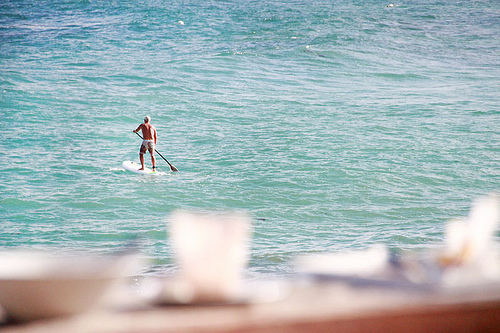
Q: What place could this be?
A: It is an ocean.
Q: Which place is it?
A: It is an ocean.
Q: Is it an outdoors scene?
A: Yes, it is outdoors.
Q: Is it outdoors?
A: Yes, it is outdoors.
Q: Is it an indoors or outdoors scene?
A: It is outdoors.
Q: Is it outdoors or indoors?
A: It is outdoors.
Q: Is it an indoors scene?
A: No, it is outdoors.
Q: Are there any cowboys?
A: No, there are no cowboys.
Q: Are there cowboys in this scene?
A: No, there are no cowboys.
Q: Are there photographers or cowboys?
A: No, there are no cowboys or photographers.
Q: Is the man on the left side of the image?
A: Yes, the man is on the left of the image.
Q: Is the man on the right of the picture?
A: No, the man is on the left of the image.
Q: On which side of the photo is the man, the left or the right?
A: The man is on the left of the image.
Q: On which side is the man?
A: The man is on the left of the image.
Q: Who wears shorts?
A: The man wears shorts.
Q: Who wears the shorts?
A: The man wears shorts.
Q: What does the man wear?
A: The man wears shorts.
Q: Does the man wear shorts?
A: Yes, the man wears shorts.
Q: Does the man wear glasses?
A: No, the man wears shorts.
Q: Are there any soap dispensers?
A: No, there are no soap dispensers.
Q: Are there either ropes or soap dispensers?
A: No, there are no soap dispensers or ropes.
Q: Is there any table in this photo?
A: Yes, there is a table.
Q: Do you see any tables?
A: Yes, there is a table.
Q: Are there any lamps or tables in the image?
A: Yes, there is a table.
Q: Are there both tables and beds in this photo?
A: No, there is a table but no beds.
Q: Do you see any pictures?
A: No, there are no pictures.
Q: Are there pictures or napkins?
A: No, there are no pictures or napkins.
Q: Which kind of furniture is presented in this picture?
A: The furniture is a table.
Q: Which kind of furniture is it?
A: The piece of furniture is a table.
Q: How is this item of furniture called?
A: This is a table.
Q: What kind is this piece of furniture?
A: This is a table.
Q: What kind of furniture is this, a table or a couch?
A: This is a table.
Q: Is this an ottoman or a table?
A: This is a table.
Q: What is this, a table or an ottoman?
A: This is a table.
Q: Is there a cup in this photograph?
A: Yes, there is a cup.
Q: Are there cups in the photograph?
A: Yes, there is a cup.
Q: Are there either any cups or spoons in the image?
A: Yes, there is a cup.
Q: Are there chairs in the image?
A: No, there are no chairs.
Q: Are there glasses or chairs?
A: No, there are no chairs or glasses.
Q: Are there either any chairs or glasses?
A: No, there are no chairs or glasses.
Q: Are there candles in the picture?
A: No, there are no candles.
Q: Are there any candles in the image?
A: No, there are no candles.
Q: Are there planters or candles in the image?
A: No, there are no candles or planters.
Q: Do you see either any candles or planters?
A: No, there are no candles or planters.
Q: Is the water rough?
A: Yes, the water is rough.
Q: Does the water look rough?
A: Yes, the water is rough.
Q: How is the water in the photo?
A: The water is rough.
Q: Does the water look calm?
A: No, the water is rough.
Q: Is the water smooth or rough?
A: The water is rough.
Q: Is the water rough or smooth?
A: The water is rough.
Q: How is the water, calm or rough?
A: The water is rough.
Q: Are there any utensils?
A: No, there are no utensils.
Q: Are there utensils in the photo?
A: No, there are no utensils.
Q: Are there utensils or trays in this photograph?
A: No, there are no utensils or trays.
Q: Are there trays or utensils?
A: No, there are no utensils or trays.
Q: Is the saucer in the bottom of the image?
A: Yes, the saucer is in the bottom of the image.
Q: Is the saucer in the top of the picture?
A: No, the saucer is in the bottom of the image.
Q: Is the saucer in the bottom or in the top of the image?
A: The saucer is in the bottom of the image.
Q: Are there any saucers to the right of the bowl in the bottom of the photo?
A: Yes, there is a saucer to the right of the bowl.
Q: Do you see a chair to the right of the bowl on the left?
A: No, there is a saucer to the right of the bowl.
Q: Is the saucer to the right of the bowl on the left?
A: Yes, the saucer is to the right of the bowl.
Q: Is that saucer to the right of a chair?
A: No, the saucer is to the right of the bowl.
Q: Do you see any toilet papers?
A: No, there are no toilet papers.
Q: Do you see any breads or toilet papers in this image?
A: No, there are no toilet papers or breads.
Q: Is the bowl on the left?
A: Yes, the bowl is on the left of the image.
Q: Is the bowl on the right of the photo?
A: No, the bowl is on the left of the image.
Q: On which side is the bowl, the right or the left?
A: The bowl is on the left of the image.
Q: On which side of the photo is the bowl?
A: The bowl is on the left of the image.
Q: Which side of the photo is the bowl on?
A: The bowl is on the left of the image.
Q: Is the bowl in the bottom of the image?
A: Yes, the bowl is in the bottom of the image.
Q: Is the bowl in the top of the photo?
A: No, the bowl is in the bottom of the image.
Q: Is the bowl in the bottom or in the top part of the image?
A: The bowl is in the bottom of the image.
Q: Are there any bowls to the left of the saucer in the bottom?
A: Yes, there is a bowl to the left of the saucer.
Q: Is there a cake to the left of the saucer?
A: No, there is a bowl to the left of the saucer.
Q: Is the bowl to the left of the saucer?
A: Yes, the bowl is to the left of the saucer.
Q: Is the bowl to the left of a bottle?
A: No, the bowl is to the left of the saucer.